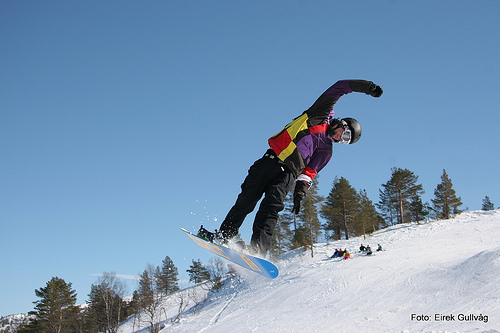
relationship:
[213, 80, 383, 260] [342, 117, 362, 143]
athlete wearing helmet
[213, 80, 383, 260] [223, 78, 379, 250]
athlete wearing coat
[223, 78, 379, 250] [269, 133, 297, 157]
coat has block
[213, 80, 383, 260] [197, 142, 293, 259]
athlete wearing pants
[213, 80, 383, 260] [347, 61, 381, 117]
athlete wearing gloves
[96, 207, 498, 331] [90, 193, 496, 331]
snow on mountain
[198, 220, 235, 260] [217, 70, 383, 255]
foot of person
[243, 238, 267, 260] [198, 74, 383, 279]
foot of person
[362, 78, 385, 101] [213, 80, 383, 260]
gloved hand of athlete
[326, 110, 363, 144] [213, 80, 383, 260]
head of athlete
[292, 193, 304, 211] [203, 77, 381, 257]
hand of athlete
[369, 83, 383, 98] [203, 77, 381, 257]
gloved hand of athlete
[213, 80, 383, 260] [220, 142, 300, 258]
athlete wearing pants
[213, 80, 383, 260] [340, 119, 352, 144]
athlete wearing goggles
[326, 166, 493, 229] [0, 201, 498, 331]
trees on hillside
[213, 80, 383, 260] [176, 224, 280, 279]
athlete on board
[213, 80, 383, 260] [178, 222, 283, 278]
athlete on snowboard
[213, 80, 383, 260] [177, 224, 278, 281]
athlete on snowboard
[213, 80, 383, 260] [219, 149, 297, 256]
athlete wearing black pants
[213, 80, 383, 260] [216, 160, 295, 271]
athlete wearing pants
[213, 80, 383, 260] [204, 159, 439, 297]
athlete wearing pants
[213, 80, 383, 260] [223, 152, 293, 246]
athlete wearing black pants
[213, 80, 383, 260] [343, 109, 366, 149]
athlete wearing helmet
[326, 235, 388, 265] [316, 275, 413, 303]
skiers in snow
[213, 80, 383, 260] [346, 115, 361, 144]
athlete wearing helmet